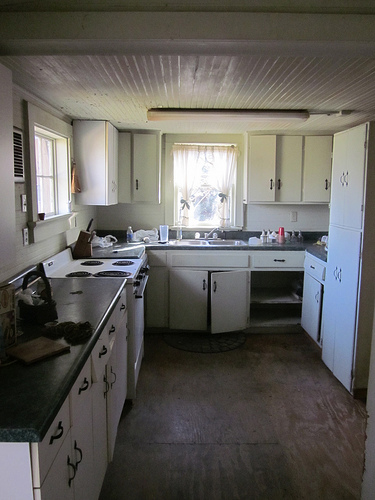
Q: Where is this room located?
A: The kitchen inside a house.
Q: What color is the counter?
A: Green.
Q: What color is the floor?
A: Brown.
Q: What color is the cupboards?
A: White.